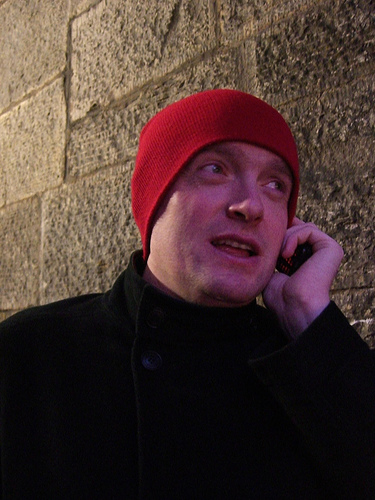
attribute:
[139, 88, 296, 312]
man — talking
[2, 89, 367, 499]
man — talking, standing, looking away, smiling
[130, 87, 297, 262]
bennie — red, warm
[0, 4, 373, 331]
wall — bricked, made out of stones, stoned, stone, brown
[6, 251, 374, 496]
coat — black, thick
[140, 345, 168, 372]
button — black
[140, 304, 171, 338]
button — black, up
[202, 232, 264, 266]
mouth — open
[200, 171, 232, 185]
bag — puffy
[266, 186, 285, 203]
bag — puffy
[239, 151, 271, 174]
hairs — un tweezed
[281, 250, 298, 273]
buttons — orange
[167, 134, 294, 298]
face — caucasian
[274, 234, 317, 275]
cellphone — black